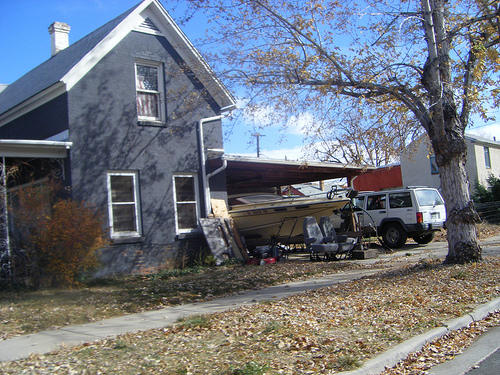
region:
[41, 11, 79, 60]
White chimney on roof of house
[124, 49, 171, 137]
White window on side of house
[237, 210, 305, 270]
Lawn mower on side of house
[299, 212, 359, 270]
Two seats in someone's yard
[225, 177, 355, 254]
The front of a boat in someones yard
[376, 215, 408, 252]
The left rear wheel on a jeep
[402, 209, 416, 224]
Gas tank on a jeep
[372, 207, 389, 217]
A black door handle on a white jeep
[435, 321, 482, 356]
Leaves on the curb near street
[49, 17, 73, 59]
chimney on house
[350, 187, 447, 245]
part of white truck in driveway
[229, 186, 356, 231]
tan boat in driveway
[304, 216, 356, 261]
two gray seats in front of boat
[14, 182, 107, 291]
reddish shrub next to house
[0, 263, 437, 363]
sidewalk in front of house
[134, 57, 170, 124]
top window with American flag in it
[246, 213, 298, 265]
red lawn mower next to seats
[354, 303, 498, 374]
curb in front of house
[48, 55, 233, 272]
grey exterior on house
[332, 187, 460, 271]
white truck outside house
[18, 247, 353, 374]
grey sidewalk outside house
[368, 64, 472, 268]
grey trunk of tree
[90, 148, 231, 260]
white windows on house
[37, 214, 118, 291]
brown bush outside house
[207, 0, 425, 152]
few leaves on tall tree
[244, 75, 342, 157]
few clouds in sky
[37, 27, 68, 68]
white chimney on roof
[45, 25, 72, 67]
white chimney on roof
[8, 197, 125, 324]
orange bush outside house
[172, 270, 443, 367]
brown leaves on ground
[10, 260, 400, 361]
grey sidewalk outside house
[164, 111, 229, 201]
white gutters on house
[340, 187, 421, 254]
white truck outside house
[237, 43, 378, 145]
blue and white sky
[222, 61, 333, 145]
few clouds in sky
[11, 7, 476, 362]
house in a rural environment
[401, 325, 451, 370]
fallen leaves in the curb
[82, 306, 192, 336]
sidewalk parallel to the street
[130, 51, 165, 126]
American flag hanging in the window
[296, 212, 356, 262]
two gray seats in the driveway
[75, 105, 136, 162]
shadow of branches on the house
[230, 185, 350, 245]
speedboat parked under the carport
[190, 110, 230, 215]
drainpipe running along the side of the house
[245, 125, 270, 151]
telephone pole in the distance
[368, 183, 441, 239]
SUV parked in the driveway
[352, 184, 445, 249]
the suv is white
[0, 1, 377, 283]
the boat is parked next to the gray house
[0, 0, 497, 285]
the tall tree in front of the house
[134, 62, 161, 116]
a window on a building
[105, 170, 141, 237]
a window on a building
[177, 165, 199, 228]
a window on a building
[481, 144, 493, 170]
a window on a building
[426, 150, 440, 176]
a window on a building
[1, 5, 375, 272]
a house on a street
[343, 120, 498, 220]
a house on a street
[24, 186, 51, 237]
a window on a building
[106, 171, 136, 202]
A window on a building.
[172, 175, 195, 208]
A window on a building.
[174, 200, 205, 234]
A window on a building.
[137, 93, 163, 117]
A window on a building.